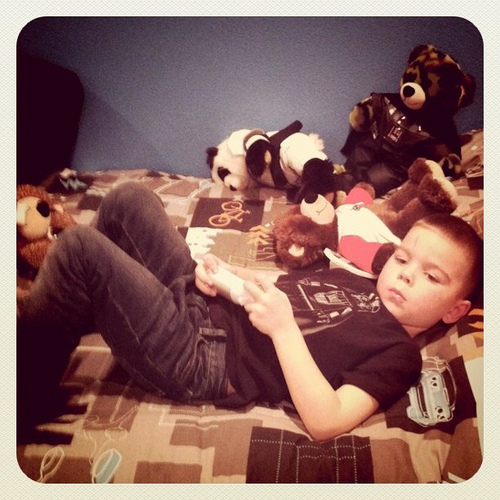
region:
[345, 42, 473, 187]
Dark brown teddy bear with black outfit.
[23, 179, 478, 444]
Little boy laying bed.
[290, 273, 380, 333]
Picture of Darth Vader on t shirt.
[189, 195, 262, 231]
Bicycle drawing on the bed.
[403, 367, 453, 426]
A car drawing on the bed.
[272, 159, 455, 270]
Brown teddy bear with white and pink shirt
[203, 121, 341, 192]
Black and white teddy bear.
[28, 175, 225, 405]
A pair of jeans worn by little boy.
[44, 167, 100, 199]
Drawing of football on bed.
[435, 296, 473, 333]
Ear of little boy on bed.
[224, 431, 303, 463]
brown color on sheet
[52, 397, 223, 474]
tan cross on bed spread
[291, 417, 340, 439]
boy's elbow on sheet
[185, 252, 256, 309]
remote in boy's hand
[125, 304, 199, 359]
wrinkles in boy's jeans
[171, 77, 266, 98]
blue walls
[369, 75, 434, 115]
white and black nose on beer's face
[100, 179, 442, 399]
boy laying on bed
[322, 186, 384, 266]
pink shirt on teddy bear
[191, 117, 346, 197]
white bear laying on it's side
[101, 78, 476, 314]
Stuffed animals in the back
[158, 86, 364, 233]
A panda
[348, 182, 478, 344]
Boy is looking elsewhere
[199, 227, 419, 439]
Has a black shirt on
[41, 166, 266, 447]
He is wearing jeans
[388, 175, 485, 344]
Has shirt hair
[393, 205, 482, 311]
Hair is brown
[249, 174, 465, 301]
Brown stuffed animal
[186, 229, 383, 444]
He is playing a game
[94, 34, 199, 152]
Wall is blue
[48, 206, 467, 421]
One boy is lying in bed.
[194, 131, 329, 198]
Panda is white and black color.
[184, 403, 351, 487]
Bed sheet is brown color.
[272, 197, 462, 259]
Boy is wearing black shirt.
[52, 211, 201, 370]
Boy is wearing black pant.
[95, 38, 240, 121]
Wall is blue color.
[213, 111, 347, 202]
Panda is in bed.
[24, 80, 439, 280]
Three teddy is in bed.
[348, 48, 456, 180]
Teddy is brown in color.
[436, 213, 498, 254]
Boy hair is brown color.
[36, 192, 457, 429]
boy laying on a bed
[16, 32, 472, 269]
four teddy bears laying on a bed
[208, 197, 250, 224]
bicycle graphic on the bedspread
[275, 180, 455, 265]
teddy bear wearing a red and white shirt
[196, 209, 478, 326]
boy holding a wii remote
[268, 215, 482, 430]
boy wearing a black t-shirt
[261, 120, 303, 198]
teddy bear wearing a black belt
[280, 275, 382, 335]
Darth Vadar graphic on a black t-shirt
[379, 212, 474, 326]
boy with short hair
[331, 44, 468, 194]
teddy bear dressed like Darth Vadar